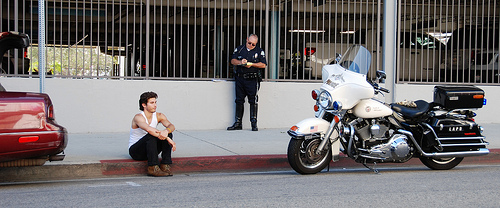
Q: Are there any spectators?
A: No, there are no spectators.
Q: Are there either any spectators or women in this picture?
A: No, there are no spectators or women.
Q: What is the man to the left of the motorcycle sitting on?
A: The man is sitting on the sidewalk.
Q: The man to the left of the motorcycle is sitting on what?
A: The man is sitting on the sidewalk.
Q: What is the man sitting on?
A: The man is sitting on the sidewalk.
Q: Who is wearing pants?
A: The man is wearing pants.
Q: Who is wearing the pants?
A: The man is wearing pants.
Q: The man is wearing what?
A: The man is wearing trousers.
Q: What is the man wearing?
A: The man is wearing trousers.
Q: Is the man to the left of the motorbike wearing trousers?
A: Yes, the man is wearing trousers.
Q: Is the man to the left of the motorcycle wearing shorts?
A: No, the man is wearing trousers.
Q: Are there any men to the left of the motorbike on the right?
A: Yes, there is a man to the left of the motorcycle.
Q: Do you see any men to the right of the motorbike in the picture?
A: No, the man is to the left of the motorbike.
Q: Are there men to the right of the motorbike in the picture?
A: No, the man is to the left of the motorbike.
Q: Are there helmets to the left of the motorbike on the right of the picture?
A: No, there is a man to the left of the motorbike.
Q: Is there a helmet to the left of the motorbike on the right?
A: No, there is a man to the left of the motorbike.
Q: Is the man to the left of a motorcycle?
A: Yes, the man is to the left of a motorcycle.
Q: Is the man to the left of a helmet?
A: No, the man is to the left of a motorcycle.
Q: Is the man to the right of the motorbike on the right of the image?
A: No, the man is to the left of the motorcycle.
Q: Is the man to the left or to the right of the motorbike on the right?
A: The man is to the left of the motorcycle.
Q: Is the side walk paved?
A: Yes, the side walk is paved.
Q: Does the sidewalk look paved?
A: Yes, the sidewalk is paved.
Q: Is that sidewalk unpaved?
A: No, the sidewalk is paved.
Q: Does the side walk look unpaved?
A: No, the side walk is paved.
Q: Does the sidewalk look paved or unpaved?
A: The sidewalk is paved.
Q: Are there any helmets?
A: No, there are no helmets.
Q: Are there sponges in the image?
A: No, there are no sponges.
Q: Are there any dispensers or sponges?
A: No, there are no sponges or dispensers.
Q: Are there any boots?
A: Yes, there are boots.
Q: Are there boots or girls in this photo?
A: Yes, there are boots.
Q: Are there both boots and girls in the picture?
A: No, there are boots but no girls.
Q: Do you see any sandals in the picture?
A: No, there are no sandals.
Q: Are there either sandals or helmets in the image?
A: No, there are no sandals or helmets.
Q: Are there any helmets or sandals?
A: No, there are no sandals or helmets.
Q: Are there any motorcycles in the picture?
A: Yes, there is a motorcycle.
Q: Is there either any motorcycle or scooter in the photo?
A: Yes, there is a motorcycle.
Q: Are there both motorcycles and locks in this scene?
A: No, there is a motorcycle but no locks.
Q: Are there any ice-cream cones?
A: No, there are no ice-cream cones.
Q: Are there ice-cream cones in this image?
A: No, there are no ice-cream cones.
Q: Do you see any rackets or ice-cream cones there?
A: No, there are no ice-cream cones or rackets.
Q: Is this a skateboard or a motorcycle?
A: This is a motorcycle.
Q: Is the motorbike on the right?
A: Yes, the motorbike is on the right of the image.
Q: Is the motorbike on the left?
A: No, the motorbike is on the right of the image.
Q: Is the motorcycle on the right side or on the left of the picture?
A: The motorcycle is on the right of the image.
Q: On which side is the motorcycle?
A: The motorcycle is on the right of the image.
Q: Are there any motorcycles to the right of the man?
A: Yes, there is a motorcycle to the right of the man.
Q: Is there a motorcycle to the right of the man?
A: Yes, there is a motorcycle to the right of the man.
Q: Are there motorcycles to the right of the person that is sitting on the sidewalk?
A: Yes, there is a motorcycle to the right of the man.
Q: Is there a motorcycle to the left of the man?
A: No, the motorcycle is to the right of the man.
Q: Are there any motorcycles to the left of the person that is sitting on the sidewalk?
A: No, the motorcycle is to the right of the man.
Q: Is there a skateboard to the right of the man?
A: No, there is a motorcycle to the right of the man.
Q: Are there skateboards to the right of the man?
A: No, there is a motorcycle to the right of the man.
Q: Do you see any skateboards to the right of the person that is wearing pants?
A: No, there is a motorcycle to the right of the man.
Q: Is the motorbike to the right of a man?
A: Yes, the motorbike is to the right of a man.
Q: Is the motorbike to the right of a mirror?
A: No, the motorbike is to the right of a man.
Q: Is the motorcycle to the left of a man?
A: No, the motorcycle is to the right of a man.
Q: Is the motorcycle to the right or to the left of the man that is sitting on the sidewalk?
A: The motorcycle is to the right of the man.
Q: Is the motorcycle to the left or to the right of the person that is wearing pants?
A: The motorcycle is to the right of the man.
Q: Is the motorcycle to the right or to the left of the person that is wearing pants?
A: The motorcycle is to the right of the man.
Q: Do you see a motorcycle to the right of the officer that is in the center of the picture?
A: Yes, there is a motorcycle to the right of the officer.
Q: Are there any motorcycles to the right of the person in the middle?
A: Yes, there is a motorcycle to the right of the officer.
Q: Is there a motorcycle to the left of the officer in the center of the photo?
A: No, the motorcycle is to the right of the officer.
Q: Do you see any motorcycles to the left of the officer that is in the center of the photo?
A: No, the motorcycle is to the right of the officer.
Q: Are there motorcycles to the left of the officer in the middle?
A: No, the motorcycle is to the right of the officer.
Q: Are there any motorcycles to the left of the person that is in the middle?
A: No, the motorcycle is to the right of the officer.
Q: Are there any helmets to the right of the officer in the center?
A: No, there is a motorcycle to the right of the officer.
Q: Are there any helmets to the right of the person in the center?
A: No, there is a motorcycle to the right of the officer.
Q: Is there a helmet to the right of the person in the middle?
A: No, there is a motorcycle to the right of the officer.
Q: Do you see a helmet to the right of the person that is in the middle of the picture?
A: No, there is a motorcycle to the right of the officer.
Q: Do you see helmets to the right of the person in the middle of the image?
A: No, there is a motorcycle to the right of the officer.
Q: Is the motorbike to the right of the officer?
A: Yes, the motorbike is to the right of the officer.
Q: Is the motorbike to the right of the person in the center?
A: Yes, the motorbike is to the right of the officer.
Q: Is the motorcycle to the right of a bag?
A: No, the motorcycle is to the right of the officer.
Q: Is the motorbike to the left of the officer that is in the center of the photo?
A: No, the motorbike is to the right of the officer.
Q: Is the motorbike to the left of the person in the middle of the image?
A: No, the motorbike is to the right of the officer.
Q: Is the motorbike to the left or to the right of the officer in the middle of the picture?
A: The motorbike is to the right of the officer.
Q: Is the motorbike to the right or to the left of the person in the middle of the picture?
A: The motorbike is to the right of the officer.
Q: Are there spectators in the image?
A: No, there are no spectators.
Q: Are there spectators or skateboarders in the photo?
A: No, there are no spectators or skateboarders.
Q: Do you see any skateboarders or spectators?
A: No, there are no spectators or skateboarders.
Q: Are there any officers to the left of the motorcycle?
A: Yes, there is an officer to the left of the motorcycle.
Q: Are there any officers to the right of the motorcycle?
A: No, the officer is to the left of the motorcycle.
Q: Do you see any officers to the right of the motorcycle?
A: No, the officer is to the left of the motorcycle.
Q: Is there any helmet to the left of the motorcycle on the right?
A: No, there is an officer to the left of the motorbike.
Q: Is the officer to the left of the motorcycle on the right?
A: Yes, the officer is to the left of the motorbike.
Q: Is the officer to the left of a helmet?
A: No, the officer is to the left of the motorbike.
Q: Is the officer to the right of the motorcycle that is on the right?
A: No, the officer is to the left of the motorcycle.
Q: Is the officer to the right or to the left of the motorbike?
A: The officer is to the left of the motorbike.